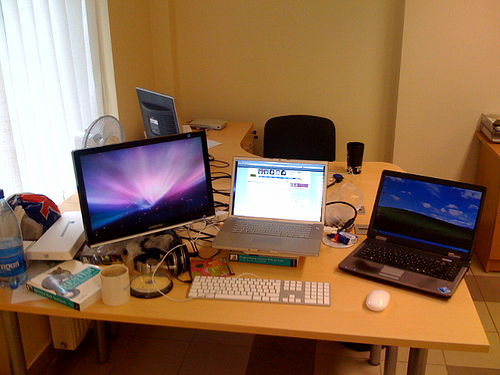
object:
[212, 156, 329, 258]
laptop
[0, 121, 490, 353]
desk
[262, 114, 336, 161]
chair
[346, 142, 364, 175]
cup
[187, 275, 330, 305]
keyboard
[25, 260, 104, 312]
book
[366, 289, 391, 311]
mouse